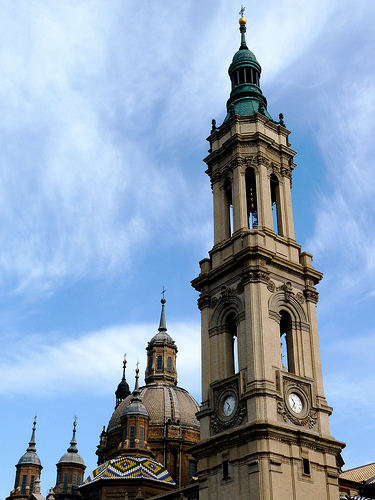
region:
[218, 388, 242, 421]
white clock face in tower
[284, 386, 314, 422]
white clock face in tower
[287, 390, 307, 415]
black roman numerals on clock face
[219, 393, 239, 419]
black roman numerals on clock face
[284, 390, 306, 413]
6:55 time read on clock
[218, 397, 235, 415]
6:55 time read on clock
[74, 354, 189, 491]
turret tiled in black, blue, white and yellow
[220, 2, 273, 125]
green turret top to large stone tower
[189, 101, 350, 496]
large stone tower with two visible clock faces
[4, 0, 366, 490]
bright blue sunny sky with clouds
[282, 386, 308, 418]
Church clock in the sun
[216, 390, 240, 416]
Church clock in the shadow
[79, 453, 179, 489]
Church roof with decorative design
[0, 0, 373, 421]
Partly cloudy sky above a church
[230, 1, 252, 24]
Cross on top of a steeple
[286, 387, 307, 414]
Clock reading 10:35 in the morning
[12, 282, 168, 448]
Several steeples with crosses on top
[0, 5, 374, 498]
Large cathedral under a partly cloudy sky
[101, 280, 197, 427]
Ornate cathedral steeple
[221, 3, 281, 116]
Copper and gold steeple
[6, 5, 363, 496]
Church spires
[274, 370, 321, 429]
Clock on a church steeple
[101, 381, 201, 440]
dome of a church steeple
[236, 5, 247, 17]
Cross on top of the church tower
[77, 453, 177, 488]
decorative colored tile on a church roof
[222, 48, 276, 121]
metal architectural element of a church steeple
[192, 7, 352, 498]
church bell tower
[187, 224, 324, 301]
stone masonry detail work on church steeple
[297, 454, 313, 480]
small window in the church tower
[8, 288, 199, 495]
four church steeples with rounded roofs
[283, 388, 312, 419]
a clock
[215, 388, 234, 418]
clock on the side of the building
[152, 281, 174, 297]
a cross on the building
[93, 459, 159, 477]
a design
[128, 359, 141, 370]
a small cross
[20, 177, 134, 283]
the white clouds in the sky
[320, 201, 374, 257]
a cloud that is white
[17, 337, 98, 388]
a cloud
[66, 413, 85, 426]
a cross in the sky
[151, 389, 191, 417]
the roof of the building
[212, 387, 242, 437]
a clock on a tower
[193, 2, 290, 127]
the top of a tower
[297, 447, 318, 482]
a small window in th etower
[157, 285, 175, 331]
a cross at the top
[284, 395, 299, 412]
hands on a clock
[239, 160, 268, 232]
pillars in the top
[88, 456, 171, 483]
a black yellow blue roof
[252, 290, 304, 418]
a concrete arch way on the tower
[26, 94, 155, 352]
a blue and white sky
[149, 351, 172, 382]
small windows in a tower